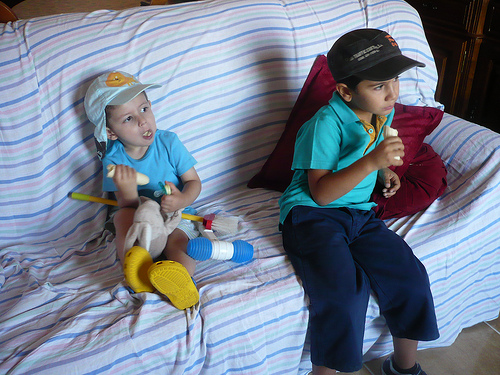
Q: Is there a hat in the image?
A: Yes, there is a hat.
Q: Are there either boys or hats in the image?
A: Yes, there is a hat.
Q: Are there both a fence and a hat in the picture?
A: No, there is a hat but no fences.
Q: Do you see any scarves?
A: No, there are no scarves.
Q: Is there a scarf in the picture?
A: No, there are no scarves.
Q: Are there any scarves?
A: No, there are no scarves.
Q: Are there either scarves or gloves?
A: No, there are no scarves or gloves.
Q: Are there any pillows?
A: Yes, there is a pillow.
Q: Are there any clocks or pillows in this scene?
A: Yes, there is a pillow.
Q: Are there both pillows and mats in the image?
A: No, there is a pillow but no mats.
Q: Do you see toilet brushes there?
A: No, there are no toilet brushes.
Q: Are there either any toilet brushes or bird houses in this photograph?
A: No, there are no toilet brushes or bird houses.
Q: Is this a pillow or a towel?
A: This is a pillow.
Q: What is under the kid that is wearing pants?
A: The pillow is under the child.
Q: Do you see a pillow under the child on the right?
A: Yes, there is a pillow under the kid.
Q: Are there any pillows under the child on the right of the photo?
A: Yes, there is a pillow under the kid.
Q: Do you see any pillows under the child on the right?
A: Yes, there is a pillow under the kid.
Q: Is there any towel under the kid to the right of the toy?
A: No, there is a pillow under the child.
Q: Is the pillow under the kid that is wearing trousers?
A: Yes, the pillow is under the child.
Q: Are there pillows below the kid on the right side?
A: Yes, there is a pillow below the kid.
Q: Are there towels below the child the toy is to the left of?
A: No, there is a pillow below the kid.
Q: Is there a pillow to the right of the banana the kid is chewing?
A: Yes, there is a pillow to the right of the banana.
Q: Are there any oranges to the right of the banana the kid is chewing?
A: No, there is a pillow to the right of the banana.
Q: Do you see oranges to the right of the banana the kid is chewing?
A: No, there is a pillow to the right of the banana.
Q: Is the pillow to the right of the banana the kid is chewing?
A: Yes, the pillow is to the right of the banana.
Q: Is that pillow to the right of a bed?
A: No, the pillow is to the right of the banana.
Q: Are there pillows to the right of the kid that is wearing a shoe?
A: Yes, there is a pillow to the right of the kid.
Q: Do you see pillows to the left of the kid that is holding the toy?
A: No, the pillow is to the right of the kid.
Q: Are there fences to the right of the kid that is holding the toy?
A: No, there is a pillow to the right of the child.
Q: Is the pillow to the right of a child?
A: Yes, the pillow is to the right of a child.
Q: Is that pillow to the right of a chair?
A: No, the pillow is to the right of a child.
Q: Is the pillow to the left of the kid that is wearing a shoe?
A: No, the pillow is to the right of the kid.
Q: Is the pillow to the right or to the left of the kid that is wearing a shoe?
A: The pillow is to the right of the kid.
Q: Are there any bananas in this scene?
A: Yes, there is a banana.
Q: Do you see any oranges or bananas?
A: Yes, there is a banana.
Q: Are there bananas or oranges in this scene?
A: Yes, there is a banana.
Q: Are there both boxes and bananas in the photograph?
A: No, there is a banana but no boxes.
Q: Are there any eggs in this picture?
A: No, there are no eggs.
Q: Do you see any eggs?
A: No, there are no eggs.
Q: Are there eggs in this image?
A: No, there are no eggs.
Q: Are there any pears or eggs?
A: No, there are no eggs or pears.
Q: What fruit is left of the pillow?
A: The fruit is a banana.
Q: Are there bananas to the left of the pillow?
A: Yes, there is a banana to the left of the pillow.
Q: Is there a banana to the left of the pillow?
A: Yes, there is a banana to the left of the pillow.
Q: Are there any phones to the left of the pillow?
A: No, there is a banana to the left of the pillow.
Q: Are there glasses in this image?
A: No, there are no glasses.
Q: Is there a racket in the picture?
A: No, there are no rackets.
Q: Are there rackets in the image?
A: No, there are no rackets.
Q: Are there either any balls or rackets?
A: No, there are no rackets or balls.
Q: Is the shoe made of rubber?
A: Yes, the shoe is made of rubber.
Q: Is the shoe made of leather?
A: No, the shoe is made of rubber.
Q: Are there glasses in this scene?
A: No, there are no glasses.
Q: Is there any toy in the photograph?
A: Yes, there is a toy.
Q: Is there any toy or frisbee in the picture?
A: Yes, there is a toy.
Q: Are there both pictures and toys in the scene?
A: No, there is a toy but no pictures.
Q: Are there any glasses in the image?
A: No, there are no glasses.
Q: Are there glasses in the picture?
A: No, there are no glasses.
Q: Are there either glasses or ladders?
A: No, there are no glasses or ladders.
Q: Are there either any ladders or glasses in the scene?
A: No, there are no glasses or ladders.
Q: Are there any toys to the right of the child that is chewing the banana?
A: Yes, there is a toy to the right of the child.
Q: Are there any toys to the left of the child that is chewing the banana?
A: No, the toy is to the right of the kid.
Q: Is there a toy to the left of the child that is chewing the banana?
A: No, the toy is to the right of the kid.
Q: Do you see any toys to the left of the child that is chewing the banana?
A: No, the toy is to the right of the kid.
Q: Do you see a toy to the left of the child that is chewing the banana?
A: No, the toy is to the right of the kid.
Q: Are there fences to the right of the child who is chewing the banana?
A: No, there is a toy to the right of the child.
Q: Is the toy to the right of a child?
A: Yes, the toy is to the right of a child.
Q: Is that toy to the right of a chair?
A: No, the toy is to the right of a child.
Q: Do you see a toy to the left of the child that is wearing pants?
A: Yes, there is a toy to the left of the kid.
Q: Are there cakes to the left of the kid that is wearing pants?
A: No, there is a toy to the left of the kid.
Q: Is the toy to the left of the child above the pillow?
A: Yes, the toy is to the left of the kid.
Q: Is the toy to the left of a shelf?
A: No, the toy is to the left of the kid.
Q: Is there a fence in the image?
A: No, there are no fences.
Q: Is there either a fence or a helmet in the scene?
A: No, there are no fences or helmets.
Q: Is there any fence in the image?
A: No, there are no fences.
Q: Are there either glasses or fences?
A: No, there are no fences or glasses.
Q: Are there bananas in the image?
A: Yes, there is a banana.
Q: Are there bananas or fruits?
A: Yes, there is a banana.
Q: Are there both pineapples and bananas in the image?
A: No, there is a banana but no pineapples.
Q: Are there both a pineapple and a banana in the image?
A: No, there is a banana but no pineapples.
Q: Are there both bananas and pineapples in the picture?
A: No, there is a banana but no pineapples.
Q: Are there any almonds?
A: No, there are no almonds.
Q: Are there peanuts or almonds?
A: No, there are no almonds or peanuts.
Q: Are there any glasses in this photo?
A: No, there are no glasses.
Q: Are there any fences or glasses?
A: No, there are no glasses or fences.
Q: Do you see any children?
A: Yes, there is a child.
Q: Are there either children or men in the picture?
A: Yes, there is a child.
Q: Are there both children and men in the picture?
A: No, there is a child but no men.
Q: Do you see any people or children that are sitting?
A: Yes, the child is sitting.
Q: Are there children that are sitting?
A: Yes, there is a child that is sitting.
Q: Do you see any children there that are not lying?
A: Yes, there is a child that is sitting .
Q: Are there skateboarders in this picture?
A: No, there are no skateboarders.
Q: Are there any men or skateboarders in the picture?
A: No, there are no skateboarders or men.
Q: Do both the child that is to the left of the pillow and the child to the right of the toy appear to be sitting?
A: Yes, both the kid and the kid are sitting.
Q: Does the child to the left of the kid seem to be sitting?
A: Yes, the child is sitting.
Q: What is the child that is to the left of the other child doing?
A: The child is sitting.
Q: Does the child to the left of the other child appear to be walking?
A: No, the child is sitting.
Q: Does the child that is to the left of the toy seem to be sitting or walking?
A: The kid is sitting.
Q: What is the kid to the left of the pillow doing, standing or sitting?
A: The kid is sitting.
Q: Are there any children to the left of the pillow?
A: Yes, there is a child to the left of the pillow.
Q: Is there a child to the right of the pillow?
A: No, the child is to the left of the pillow.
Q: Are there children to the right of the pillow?
A: No, the child is to the left of the pillow.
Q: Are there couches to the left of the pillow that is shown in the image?
A: No, there is a child to the left of the pillow.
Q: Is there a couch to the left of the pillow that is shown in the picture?
A: No, there is a child to the left of the pillow.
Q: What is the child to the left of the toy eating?
A: The child is eating a banana.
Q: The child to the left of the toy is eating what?
A: The child is eating a banana.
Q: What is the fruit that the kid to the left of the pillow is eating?
A: The fruit is a banana.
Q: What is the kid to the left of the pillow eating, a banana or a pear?
A: The kid is eating a banana.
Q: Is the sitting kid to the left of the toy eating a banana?
A: Yes, the kid is eating a banana.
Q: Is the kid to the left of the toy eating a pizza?
A: No, the child is eating a banana.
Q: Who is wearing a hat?
A: The child is wearing a hat.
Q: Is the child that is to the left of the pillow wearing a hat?
A: Yes, the kid is wearing a hat.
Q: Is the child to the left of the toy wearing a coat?
A: No, the kid is wearing a hat.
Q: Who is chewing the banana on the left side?
A: The kid is chewing the banana.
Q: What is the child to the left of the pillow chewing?
A: The child is chewing the banana.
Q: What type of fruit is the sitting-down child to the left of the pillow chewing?
A: The kid is chewing the banana.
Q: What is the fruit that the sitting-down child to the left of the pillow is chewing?
A: The fruit is a banana.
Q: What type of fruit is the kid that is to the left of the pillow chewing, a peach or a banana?
A: The child is chewing a banana.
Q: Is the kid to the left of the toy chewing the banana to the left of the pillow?
A: Yes, the child is chewing the banana.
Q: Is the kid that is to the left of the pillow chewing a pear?
A: No, the kid is chewing the banana.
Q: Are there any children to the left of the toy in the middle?
A: Yes, there is a child to the left of the toy.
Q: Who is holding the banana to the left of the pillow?
A: The child is holding the banana.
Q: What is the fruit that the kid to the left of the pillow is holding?
A: The fruit is a banana.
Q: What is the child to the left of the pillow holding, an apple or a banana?
A: The child is holding a banana.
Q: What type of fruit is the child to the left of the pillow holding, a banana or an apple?
A: The child is holding a banana.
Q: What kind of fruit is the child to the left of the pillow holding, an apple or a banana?
A: The child is holding a banana.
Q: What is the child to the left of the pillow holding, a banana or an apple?
A: The child is holding a banana.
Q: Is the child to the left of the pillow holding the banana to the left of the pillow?
A: Yes, the child is holding the banana.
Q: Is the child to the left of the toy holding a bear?
A: No, the kid is holding the banana.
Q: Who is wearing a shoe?
A: The kid is wearing a shoe.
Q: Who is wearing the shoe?
A: The kid is wearing a shoe.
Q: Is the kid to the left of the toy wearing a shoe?
A: Yes, the kid is wearing a shoe.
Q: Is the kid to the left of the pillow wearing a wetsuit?
A: No, the child is wearing a shoe.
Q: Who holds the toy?
A: The child holds the toy.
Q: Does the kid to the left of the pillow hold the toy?
A: Yes, the kid holds the toy.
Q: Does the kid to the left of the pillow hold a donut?
A: No, the child holds the toy.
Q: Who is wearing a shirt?
A: The child is wearing a shirt.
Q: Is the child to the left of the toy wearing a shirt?
A: Yes, the kid is wearing a shirt.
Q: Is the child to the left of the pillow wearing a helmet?
A: No, the kid is wearing a shirt.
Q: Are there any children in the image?
A: Yes, there is a child.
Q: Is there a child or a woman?
A: Yes, there is a child.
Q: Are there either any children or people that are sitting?
A: Yes, the child is sitting.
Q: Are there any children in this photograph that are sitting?
A: Yes, there is a child that is sitting.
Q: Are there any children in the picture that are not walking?
A: Yes, there is a child that is sitting.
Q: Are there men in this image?
A: No, there are no men.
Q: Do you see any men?
A: No, there are no men.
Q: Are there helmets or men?
A: No, there are no men or helmets.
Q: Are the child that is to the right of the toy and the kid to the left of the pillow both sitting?
A: Yes, both the child and the kid are sitting.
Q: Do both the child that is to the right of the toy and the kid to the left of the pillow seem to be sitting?
A: Yes, both the child and the kid are sitting.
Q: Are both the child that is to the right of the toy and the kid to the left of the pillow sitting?
A: Yes, both the child and the kid are sitting.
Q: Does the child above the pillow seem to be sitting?
A: Yes, the kid is sitting.